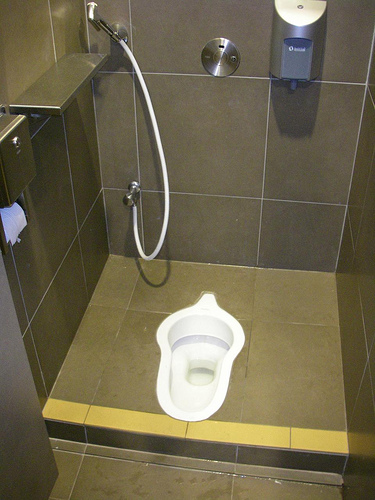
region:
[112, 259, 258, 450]
Toilet in the ground.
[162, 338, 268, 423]
Water in the toilet.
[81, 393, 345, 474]
Yellow on the floor.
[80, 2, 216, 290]
Hose on the wall.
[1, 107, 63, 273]
Toilet paper roll on the wall.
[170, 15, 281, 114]
Flush button on the wall.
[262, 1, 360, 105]
Hand sanitizer on the wall.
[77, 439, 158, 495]
Grout on the floor.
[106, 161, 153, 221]
Metal part of the hose.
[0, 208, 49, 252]
White toilet paper roll.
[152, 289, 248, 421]
toilet in shower stall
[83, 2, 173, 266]
white and silver shower hose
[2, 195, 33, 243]
toilet paper dispenser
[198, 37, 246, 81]
round silver toilet flusher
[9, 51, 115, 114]
silver metal shelf in stall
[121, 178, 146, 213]
connection for shower hose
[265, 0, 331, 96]
silver soap hand dispenser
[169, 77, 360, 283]
brown tile walls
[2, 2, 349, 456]
shower and toilet stall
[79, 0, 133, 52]
silver handle of shower hose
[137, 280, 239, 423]
the toilet is white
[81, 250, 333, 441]
the floor is tiled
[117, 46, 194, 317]
the hose is white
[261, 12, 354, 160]
the dispenser on the wall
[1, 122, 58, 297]
toilet paper on the wall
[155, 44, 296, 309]
the wall is tiled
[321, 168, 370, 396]
the wall is tiled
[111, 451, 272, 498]
the floor is tiled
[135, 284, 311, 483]
toilet seat on the ground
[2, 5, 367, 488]
an unusual bathroom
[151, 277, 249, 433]
the toilet in an unusual bathroom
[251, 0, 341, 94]
the bathroom soap dispenser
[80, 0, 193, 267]
a bathroom shower cord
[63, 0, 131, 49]
a bathroom showerhead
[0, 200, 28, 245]
a toilet paper roll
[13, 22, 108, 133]
a shelf in a bathroom shower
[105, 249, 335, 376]
a tile floor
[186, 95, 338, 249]
a tile wall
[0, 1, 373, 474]
a Japanese shower and toilet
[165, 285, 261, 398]
White toilet in floor.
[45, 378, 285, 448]
Yellow strip on brown tile.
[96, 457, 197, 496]
Brown tile makes up the floor.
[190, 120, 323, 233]
Brown tile on the wall in the bathroom.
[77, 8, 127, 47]
Silver nozzle on shower head.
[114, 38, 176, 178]
White hose on faucet.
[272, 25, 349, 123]
Gray soap dispenser in shower.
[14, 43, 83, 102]
Silver shelf attached to wall.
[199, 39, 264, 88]
Silver circle on wall.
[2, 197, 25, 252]
Toilet paper in silver dispenser.